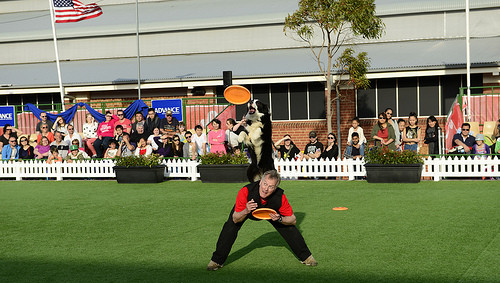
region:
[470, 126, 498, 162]
this is a person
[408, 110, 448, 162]
this is a person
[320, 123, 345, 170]
this is a person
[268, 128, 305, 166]
this is a person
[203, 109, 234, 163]
this is a person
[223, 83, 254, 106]
an orange frisbee in air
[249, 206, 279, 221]
a round orange frisbee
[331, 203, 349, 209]
a round orange frisbee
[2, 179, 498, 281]
a section of green astroturf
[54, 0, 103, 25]
an American flag waving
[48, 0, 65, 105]
a white flag pole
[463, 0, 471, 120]
a white flag pole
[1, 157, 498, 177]
a long white picket fence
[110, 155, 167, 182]
a large black planter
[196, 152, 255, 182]
a large black planter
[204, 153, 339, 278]
this is a person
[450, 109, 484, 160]
this is a person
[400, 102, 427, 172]
this is a person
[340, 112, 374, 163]
this is a person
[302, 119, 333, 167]
this is a person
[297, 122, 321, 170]
this is a person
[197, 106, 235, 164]
this is a person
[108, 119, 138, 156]
this is a person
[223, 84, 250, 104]
a orange frisbee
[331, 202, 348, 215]
a orange frisbee on the ground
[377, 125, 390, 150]
a woman wearing a red shirt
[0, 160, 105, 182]
a short white fence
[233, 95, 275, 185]
a black and white dog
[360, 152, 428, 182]
a black flower pot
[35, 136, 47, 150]
a woman wearing a purple shirt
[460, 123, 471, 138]
a man wearing sunglasses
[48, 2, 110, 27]
a red,white and blue flag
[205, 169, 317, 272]
man holding an orange frisbee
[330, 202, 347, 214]
orange frisbee laying on the ground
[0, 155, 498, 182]
short white picket fence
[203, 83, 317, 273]
dog and man performing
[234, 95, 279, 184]
black and white dog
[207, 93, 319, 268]
dog jumping over a man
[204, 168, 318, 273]
man wearing red shirt and black vest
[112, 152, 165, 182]
green plants in a black planter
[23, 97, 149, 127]
blue cloth ribbon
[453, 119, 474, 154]
man wearing sunglasses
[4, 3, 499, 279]
a scene outside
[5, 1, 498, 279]
an image at a park